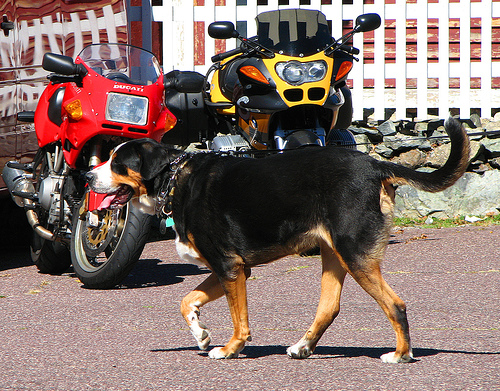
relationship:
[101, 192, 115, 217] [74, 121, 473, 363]
tongue on dog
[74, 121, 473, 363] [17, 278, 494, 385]
dog walking on pavement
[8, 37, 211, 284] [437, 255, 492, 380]
bike parked on pavement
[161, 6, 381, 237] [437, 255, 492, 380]
bike parked on pavement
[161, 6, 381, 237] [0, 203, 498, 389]
bike parked on ground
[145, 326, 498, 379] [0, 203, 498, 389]
shadow on ground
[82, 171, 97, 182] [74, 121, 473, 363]
nose on dog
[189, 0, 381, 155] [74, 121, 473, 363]
bike behind dog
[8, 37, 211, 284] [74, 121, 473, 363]
bike behind dog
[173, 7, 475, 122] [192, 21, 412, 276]
fence behind bikes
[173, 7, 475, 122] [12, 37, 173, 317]
fence behind bikes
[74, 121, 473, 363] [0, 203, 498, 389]
dog on ground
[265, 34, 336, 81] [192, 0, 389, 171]
headlight on motorcycle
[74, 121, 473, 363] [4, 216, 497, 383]
dog walking across street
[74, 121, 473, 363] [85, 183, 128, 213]
dog has tongue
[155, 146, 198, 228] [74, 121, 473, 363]
collar on dog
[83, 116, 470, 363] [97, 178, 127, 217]
dog has tongue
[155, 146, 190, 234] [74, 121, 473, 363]
collar on dog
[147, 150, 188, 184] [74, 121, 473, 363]
bandana on dog